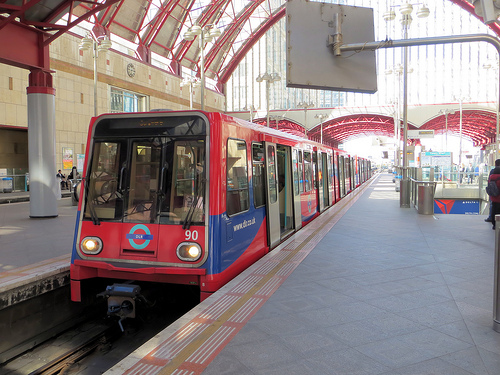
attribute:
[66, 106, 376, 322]
train — public transit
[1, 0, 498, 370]
station — train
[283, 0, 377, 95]
sign — silver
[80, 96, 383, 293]
train — red, blue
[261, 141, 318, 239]
door — open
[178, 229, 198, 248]
numbers — white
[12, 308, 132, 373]
tracks — railway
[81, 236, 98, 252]
headlight — on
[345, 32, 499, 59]
pole — gray, metal 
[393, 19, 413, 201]
pole — gray, metal 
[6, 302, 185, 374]
track — gray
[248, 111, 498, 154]
archways — red